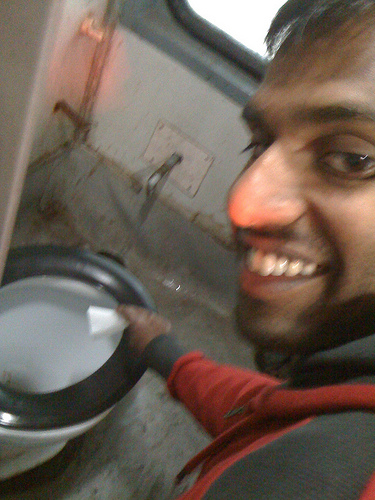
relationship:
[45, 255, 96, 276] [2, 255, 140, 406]
seat of toilet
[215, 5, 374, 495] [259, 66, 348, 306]
man has face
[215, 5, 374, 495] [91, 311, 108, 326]
man holding cloth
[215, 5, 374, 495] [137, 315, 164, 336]
man has hand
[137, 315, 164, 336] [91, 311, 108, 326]
hand holding cloth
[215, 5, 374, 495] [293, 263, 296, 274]
man has tooth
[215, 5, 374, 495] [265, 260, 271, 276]
man has tooth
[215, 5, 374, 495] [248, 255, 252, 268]
man has tooth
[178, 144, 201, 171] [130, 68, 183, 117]
plate on wall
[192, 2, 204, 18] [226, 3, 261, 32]
corner of window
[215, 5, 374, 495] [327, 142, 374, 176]
man has eye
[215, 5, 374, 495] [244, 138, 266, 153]
man has eye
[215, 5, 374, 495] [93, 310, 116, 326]
man holding tissue paper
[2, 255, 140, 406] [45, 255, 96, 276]
toilet has seat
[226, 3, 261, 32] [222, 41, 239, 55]
window has rim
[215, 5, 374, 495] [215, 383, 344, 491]
man has jacket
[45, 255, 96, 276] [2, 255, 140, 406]
seat on toilet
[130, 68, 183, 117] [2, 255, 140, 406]
wall next to toilet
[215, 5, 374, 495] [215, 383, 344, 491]
man wearing jacket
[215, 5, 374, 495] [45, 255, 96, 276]
man touching seat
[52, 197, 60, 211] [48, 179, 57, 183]
rust in corner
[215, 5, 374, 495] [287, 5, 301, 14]
man has hair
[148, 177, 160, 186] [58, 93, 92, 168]
pipe in background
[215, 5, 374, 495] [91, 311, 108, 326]
man has cloth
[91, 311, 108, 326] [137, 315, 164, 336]
cloth in hand